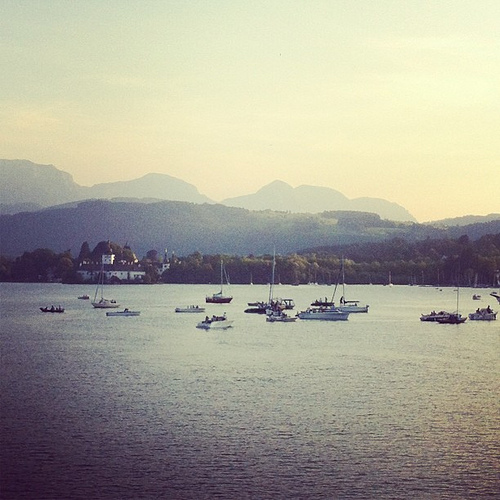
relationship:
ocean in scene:
[2, 282, 498, 494] [6, 4, 498, 496]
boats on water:
[30, 282, 499, 334] [6, 280, 493, 498]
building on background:
[73, 240, 149, 285] [12, 240, 499, 280]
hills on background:
[4, 193, 498, 291] [10, 153, 499, 283]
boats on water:
[170, 284, 375, 338] [6, 280, 493, 498]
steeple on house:
[97, 238, 117, 267] [95, 242, 149, 283]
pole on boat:
[213, 254, 225, 299] [202, 291, 234, 307]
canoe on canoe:
[39, 305, 65, 314] [39, 309, 64, 318]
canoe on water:
[39, 309, 64, 318] [21, 289, 81, 327]